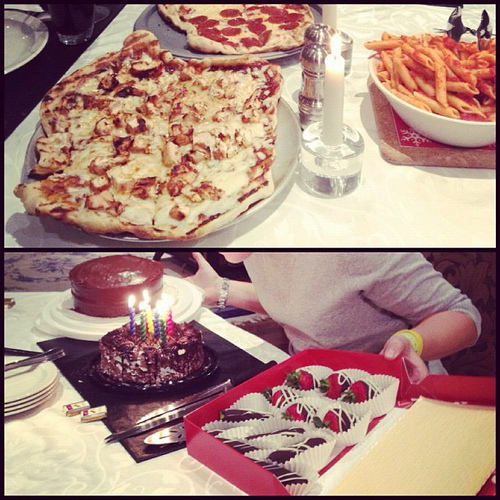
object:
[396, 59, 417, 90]
bowl noodles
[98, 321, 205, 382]
cake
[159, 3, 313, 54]
pepperoni pizza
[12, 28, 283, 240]
pizza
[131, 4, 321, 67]
plate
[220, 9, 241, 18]
toppings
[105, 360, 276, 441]
knife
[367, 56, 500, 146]
bowl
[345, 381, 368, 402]
strawberries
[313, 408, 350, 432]
strawberries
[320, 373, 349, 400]
strawberries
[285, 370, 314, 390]
strawberries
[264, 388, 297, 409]
strawberries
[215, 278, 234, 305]
wrist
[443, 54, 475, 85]
pasta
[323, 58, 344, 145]
candle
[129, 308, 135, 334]
candle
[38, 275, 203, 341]
platter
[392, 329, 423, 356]
wristband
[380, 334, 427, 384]
hand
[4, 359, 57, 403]
plate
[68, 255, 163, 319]
cake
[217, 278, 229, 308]
bracelet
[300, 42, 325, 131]
salt shakers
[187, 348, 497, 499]
red box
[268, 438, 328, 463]
cupcakes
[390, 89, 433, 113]
pasta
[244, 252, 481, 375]
shirt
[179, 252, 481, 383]
person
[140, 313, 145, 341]
candle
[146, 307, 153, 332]
candle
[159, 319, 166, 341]
candle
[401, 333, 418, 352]
bracelet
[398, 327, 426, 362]
wrist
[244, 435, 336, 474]
paper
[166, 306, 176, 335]
candle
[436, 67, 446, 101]
fries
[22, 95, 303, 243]
plate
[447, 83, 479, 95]
noodles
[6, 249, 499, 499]
table